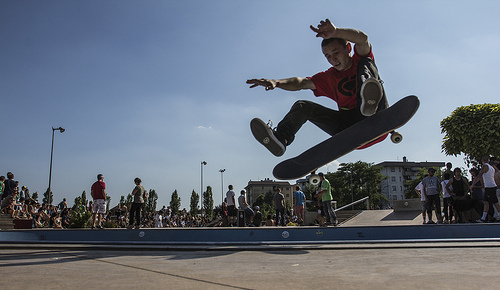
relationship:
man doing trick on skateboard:
[243, 17, 399, 156] [268, 91, 423, 185]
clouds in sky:
[133, 93, 272, 172] [0, 0, 499, 213]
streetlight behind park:
[49, 121, 64, 221] [0, 0, 499, 290]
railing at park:
[328, 192, 373, 224] [0, 0, 499, 290]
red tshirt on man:
[306, 42, 388, 148] [243, 17, 399, 157]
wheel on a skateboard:
[389, 129, 402, 144] [272, 92, 417, 179]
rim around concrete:
[49, 210, 411, 251] [7, 240, 499, 289]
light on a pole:
[53, 121, 68, 135] [34, 102, 119, 277]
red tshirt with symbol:
[306, 42, 388, 151] [334, 74, 354, 99]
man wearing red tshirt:
[243, 17, 399, 157] [306, 42, 388, 151]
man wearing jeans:
[243, 17, 399, 157] [273, 97, 390, 134]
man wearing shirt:
[243, 17, 399, 157] [306, 53, 392, 102]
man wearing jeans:
[243, 17, 399, 157] [269, 91, 395, 144]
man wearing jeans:
[243, 17, 399, 157] [276, 97, 386, 152]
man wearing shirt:
[243, 17, 399, 157] [304, 49, 380, 109]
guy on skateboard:
[231, 15, 433, 186] [268, 91, 423, 185]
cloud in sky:
[141, 88, 225, 151] [10, 9, 456, 180]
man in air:
[243, 17, 399, 157] [114, 11, 453, 191]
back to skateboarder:
[219, 177, 239, 218] [228, 29, 422, 157]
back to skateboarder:
[269, 195, 286, 211] [228, 29, 422, 157]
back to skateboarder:
[290, 189, 310, 212] [228, 29, 422, 157]